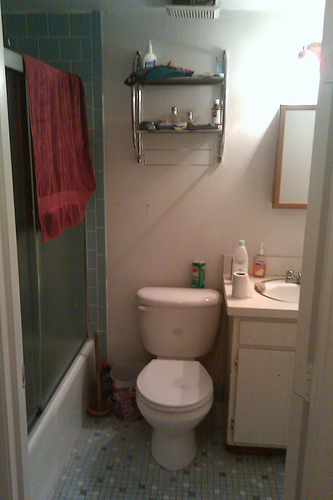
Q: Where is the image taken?
A: In washroom.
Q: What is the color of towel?
A: Maroon.